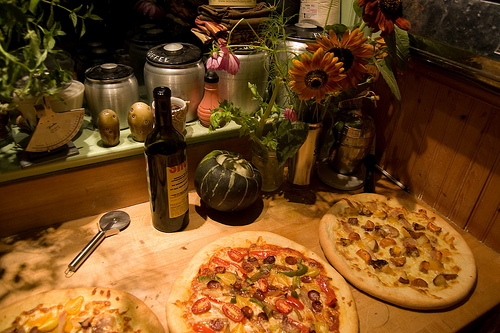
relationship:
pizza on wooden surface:
[1, 189, 492, 332] [7, 112, 500, 333]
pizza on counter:
[1, 189, 492, 332] [7, 112, 500, 333]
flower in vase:
[209, 31, 406, 122] [235, 93, 381, 187]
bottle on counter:
[149, 86, 193, 236] [7, 112, 500, 333]